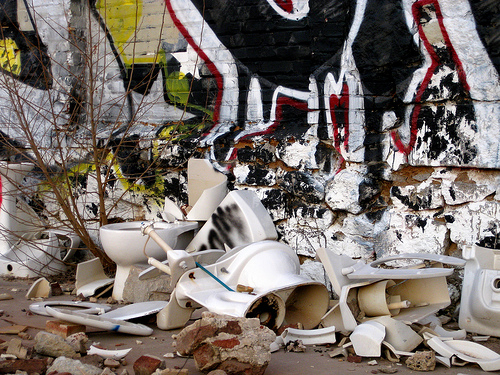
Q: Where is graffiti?
A: On wall.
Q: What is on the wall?
A: Graffiti.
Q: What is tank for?
A: Toilet.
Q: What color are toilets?
A: White.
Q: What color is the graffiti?
A: Black.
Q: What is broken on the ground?
A: Toilets.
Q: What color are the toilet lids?
A: White.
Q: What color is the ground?
A: Gray.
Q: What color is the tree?
A: Brown.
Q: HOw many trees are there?
A: One.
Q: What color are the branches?
A: Brown.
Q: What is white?
A: Wall.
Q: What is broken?
A: Toilets.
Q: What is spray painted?
A: The wall.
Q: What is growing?
A: The tree.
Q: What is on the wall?
A: Paint.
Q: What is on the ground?
A: Toilets.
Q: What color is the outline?
A: White.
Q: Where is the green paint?
A: Wall.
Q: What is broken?
A: Toilets.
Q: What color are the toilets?
A: White.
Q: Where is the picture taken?
A: On the side of a building.